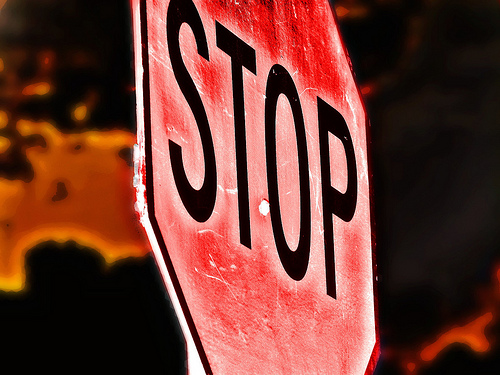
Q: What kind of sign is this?
A: A stop sign.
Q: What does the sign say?
A: Stop.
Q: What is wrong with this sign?
A: Old and scratched.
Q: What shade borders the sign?
A: Black.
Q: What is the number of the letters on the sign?
A: Four.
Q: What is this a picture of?
A: A stop sign.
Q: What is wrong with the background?
A: Not sure, to blurry.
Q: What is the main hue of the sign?
A: Red.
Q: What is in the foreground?
A: Stop sign.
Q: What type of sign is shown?
A: Stop sign.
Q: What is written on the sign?
A: Stop.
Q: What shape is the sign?
A: Octagon.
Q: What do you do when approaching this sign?
A: Stop.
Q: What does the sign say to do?
A: Stop.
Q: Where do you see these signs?
A: On streets.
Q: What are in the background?
A: Dark clouds.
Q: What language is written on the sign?
A: English.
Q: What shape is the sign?
A: Octagon.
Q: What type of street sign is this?
A: Stop sign.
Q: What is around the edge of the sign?
A: A black line.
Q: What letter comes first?
A: S.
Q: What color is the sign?
A: Red.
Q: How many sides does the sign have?
A: 8.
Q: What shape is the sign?
A: Octagon.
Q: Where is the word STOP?
A: On the sign.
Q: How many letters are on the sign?
A: 4.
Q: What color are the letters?
A: Black.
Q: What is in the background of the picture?
A: Clouds.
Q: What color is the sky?
A: Orange.